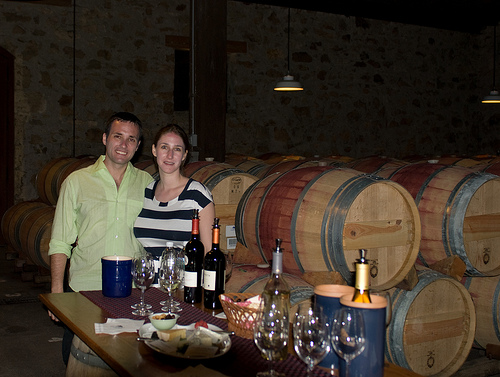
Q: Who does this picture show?
A: A couple posing.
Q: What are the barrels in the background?
A: Wine.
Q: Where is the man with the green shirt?
A: On the left.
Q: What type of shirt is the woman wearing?
A: Striped.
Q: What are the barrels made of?
A: Wood.